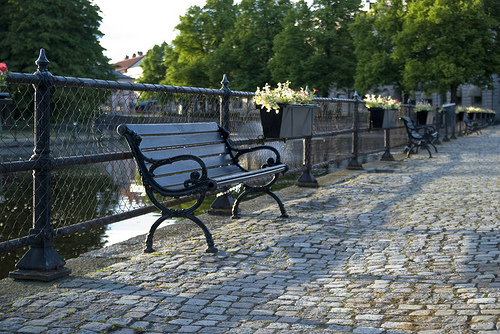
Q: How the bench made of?
A: Metal.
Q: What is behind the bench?
A: Pond.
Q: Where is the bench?
A: By the fence.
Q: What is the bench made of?
A: Wood.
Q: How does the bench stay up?
A: Legs.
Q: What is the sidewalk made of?
A: Cobblestone.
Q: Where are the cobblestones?
A: In the sidewalk.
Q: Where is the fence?
A: Behind the bench.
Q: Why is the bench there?
A: To sit on.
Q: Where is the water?
A: Behind the fence.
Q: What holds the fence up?
A: Posts.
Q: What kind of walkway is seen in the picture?
A: A brick paved walkway.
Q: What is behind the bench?
A: A fence.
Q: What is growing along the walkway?
A: Trees.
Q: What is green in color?
A: The trees.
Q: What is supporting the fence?
A: A post.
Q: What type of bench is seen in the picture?
A: Wood and metal bench.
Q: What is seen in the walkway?
A: Shadow.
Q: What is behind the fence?
A: A pond.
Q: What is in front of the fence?
A: A bench.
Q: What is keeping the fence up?
A: Pole.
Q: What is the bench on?
A: Ground.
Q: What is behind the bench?
A: Water.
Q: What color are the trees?
A: Green.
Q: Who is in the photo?
A: No one.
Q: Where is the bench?
A: On the cement.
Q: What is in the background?
A: Trees.